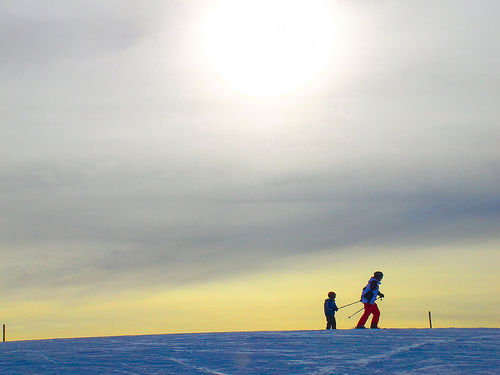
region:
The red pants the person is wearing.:
[362, 305, 377, 327]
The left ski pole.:
[338, 298, 363, 310]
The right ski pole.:
[344, 295, 377, 326]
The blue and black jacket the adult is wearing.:
[361, 279, 383, 304]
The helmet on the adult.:
[374, 271, 384, 276]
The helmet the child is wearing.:
[327, 290, 336, 297]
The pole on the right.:
[426, 307, 433, 327]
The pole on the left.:
[1, 322, 6, 342]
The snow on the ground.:
[16, 335, 498, 372]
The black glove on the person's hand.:
[379, 293, 382, 298]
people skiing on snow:
[312, 262, 394, 335]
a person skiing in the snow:
[343, 265, 389, 330]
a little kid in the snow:
[323, 288, 342, 330]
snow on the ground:
[70, 335, 460, 368]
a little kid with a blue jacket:
[323, 298, 340, 315]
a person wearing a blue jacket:
[360, 273, 379, 301]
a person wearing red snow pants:
[356, 298, 383, 330]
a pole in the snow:
[425, 308, 437, 332]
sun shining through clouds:
[175, 8, 370, 115]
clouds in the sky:
[18, 161, 480, 287]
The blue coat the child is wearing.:
[322, 298, 333, 317]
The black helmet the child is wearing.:
[327, 290, 334, 300]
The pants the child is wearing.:
[326, 317, 337, 328]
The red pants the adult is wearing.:
[361, 304, 379, 324]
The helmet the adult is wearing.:
[374, 270, 384, 277]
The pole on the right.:
[428, 310, 432, 326]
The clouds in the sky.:
[9, 3, 499, 253]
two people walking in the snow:
[299, 273, 419, 358]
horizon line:
[16, 322, 194, 353]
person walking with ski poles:
[339, 262, 391, 333]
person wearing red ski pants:
[356, 299, 390, 336]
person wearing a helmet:
[373, 268, 384, 284]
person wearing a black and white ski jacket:
[361, 276, 378, 303]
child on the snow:
[314, 288, 343, 331]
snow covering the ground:
[139, 343, 267, 373]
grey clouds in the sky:
[40, 170, 208, 250]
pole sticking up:
[420, 303, 436, 333]